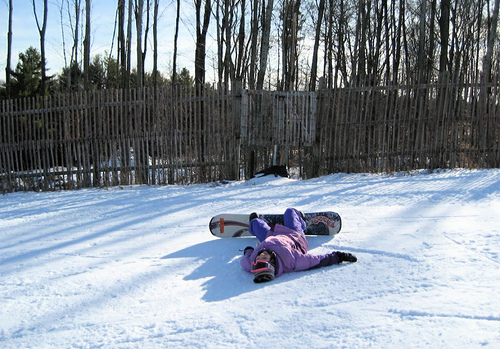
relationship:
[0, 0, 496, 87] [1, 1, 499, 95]
cloud are in blue sky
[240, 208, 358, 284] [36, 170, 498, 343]
female in snow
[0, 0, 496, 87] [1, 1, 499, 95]
cloud in blue sky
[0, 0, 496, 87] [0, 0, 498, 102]
cloud in sky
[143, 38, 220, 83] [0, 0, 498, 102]
cloud in sky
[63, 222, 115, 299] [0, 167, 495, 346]
snow on hill side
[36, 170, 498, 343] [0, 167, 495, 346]
snow on hill side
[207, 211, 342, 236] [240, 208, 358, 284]
snowboard on female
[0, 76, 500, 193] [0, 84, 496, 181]
stick on fence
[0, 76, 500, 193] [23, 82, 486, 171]
stick on fence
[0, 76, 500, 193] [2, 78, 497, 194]
stick on fence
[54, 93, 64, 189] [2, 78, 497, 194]
stick on fence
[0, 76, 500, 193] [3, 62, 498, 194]
stick on fence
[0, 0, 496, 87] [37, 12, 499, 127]
cloud in sky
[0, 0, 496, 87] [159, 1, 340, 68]
cloud in sky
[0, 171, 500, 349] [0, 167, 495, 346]
snow on hill hill side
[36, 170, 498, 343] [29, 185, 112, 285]
snow on hill side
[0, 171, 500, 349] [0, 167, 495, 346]
snow on hill side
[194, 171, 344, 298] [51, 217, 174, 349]
female lying in snow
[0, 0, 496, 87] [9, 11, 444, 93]
cloud in sky